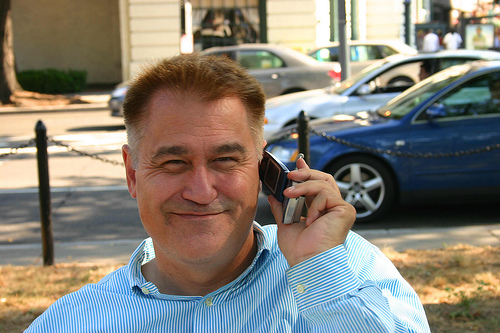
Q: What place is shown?
A: It is a street.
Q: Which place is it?
A: It is a street.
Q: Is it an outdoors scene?
A: Yes, it is outdoors.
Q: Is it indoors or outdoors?
A: It is outdoors.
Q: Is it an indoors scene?
A: No, it is outdoors.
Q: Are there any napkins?
A: No, there are no napkins.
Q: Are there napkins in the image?
A: No, there are no napkins.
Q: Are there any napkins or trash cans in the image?
A: No, there are no napkins or trash cans.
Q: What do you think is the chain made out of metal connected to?
A: The chain is connected to the post.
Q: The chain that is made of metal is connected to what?
A: The chain is connected to the post.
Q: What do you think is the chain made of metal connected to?
A: The chain is connected to the post.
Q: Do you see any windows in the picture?
A: Yes, there is a window.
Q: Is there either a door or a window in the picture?
A: Yes, there is a window.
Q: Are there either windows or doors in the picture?
A: Yes, there is a window.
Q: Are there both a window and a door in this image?
A: No, there is a window but no doors.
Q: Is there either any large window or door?
A: Yes, there is a large window.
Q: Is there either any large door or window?
A: Yes, there is a large window.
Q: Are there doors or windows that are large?
A: Yes, the window is large.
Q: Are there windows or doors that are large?
A: Yes, the window is large.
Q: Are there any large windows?
A: Yes, there is a large window.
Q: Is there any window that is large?
A: Yes, there is a large window.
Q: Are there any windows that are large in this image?
A: Yes, there is a large window.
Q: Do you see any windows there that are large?
A: Yes, there is a window that is large.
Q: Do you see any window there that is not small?
A: Yes, there is a large window.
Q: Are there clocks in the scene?
A: No, there are no clocks.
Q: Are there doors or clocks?
A: No, there are no clocks or doors.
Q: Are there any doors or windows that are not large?
A: No, there is a window but it is large.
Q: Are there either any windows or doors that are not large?
A: No, there is a window but it is large.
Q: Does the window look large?
A: Yes, the window is large.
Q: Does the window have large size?
A: Yes, the window is large.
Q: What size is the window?
A: The window is large.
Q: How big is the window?
A: The window is large.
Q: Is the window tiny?
A: No, the window is large.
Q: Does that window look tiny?
A: No, the window is large.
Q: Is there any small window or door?
A: No, there is a window but it is large.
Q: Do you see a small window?
A: No, there is a window but it is large.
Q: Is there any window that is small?
A: No, there is a window but it is large.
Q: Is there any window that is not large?
A: No, there is a window but it is large.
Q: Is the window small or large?
A: The window is large.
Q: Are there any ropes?
A: No, there are no ropes.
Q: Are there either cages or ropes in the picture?
A: No, there are no ropes or cages.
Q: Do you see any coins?
A: No, there are no coins.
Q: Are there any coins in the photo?
A: No, there are no coins.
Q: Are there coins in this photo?
A: No, there are no coins.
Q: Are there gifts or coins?
A: No, there are no coins or gifts.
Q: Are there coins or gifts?
A: No, there are no coins or gifts.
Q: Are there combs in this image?
A: No, there are no combs.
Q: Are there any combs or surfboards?
A: No, there are no combs or surfboards.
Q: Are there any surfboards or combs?
A: No, there are no combs or surfboards.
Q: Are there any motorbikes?
A: No, there are no motorbikes.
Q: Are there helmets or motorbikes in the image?
A: No, there are no motorbikes or helmets.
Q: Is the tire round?
A: Yes, the tire is round.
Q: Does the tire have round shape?
A: Yes, the tire is round.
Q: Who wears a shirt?
A: The man wears a shirt.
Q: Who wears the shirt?
A: The man wears a shirt.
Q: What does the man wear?
A: The man wears a shirt.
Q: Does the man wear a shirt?
A: Yes, the man wears a shirt.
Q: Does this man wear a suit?
A: No, the man wears a shirt.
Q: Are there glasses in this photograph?
A: No, there are no glasses.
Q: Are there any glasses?
A: No, there are no glasses.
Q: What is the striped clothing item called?
A: The clothing item is a shirt.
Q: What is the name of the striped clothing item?
A: The clothing item is a shirt.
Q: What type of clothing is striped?
A: The clothing is a shirt.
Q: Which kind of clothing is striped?
A: The clothing is a shirt.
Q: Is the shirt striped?
A: Yes, the shirt is striped.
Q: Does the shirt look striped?
A: Yes, the shirt is striped.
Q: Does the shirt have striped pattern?
A: Yes, the shirt is striped.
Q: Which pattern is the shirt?
A: The shirt is striped.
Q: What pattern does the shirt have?
A: The shirt has striped pattern.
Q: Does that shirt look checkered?
A: No, the shirt is striped.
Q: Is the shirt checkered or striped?
A: The shirt is striped.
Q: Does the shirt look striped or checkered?
A: The shirt is striped.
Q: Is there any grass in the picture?
A: Yes, there is grass.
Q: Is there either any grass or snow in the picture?
A: Yes, there is grass.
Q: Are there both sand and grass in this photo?
A: No, there is grass but no sand.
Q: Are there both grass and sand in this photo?
A: No, there is grass but no sand.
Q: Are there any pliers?
A: No, there are no pliers.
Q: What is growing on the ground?
A: The grass is growing on the ground.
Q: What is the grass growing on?
A: The grass is growing on the ground.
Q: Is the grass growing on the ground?
A: Yes, the grass is growing on the ground.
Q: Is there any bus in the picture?
A: No, there are no buses.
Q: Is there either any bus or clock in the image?
A: No, there are no buses or clocks.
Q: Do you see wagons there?
A: No, there are no wagons.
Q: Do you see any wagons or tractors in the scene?
A: No, there are no wagons or tractors.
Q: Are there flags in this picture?
A: No, there are no flags.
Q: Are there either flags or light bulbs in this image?
A: No, there are no flags or light bulbs.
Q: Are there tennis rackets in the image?
A: No, there are no tennis rackets.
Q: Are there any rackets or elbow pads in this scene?
A: No, there are no rackets or elbow pads.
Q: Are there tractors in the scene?
A: No, there are no tractors.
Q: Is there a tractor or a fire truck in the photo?
A: No, there are no tractors or fire trucks.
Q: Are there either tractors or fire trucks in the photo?
A: No, there are no tractors or fire trucks.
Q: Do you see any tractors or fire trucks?
A: No, there are no tractors or fire trucks.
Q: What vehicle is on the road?
A: The vehicle is a car.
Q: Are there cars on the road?
A: Yes, there is a car on the road.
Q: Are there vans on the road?
A: No, there is a car on the road.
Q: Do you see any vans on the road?
A: No, there is a car on the road.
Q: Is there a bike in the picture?
A: No, there are no bikes.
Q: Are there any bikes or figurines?
A: No, there are no bikes or figurines.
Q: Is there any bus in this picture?
A: No, there are no buses.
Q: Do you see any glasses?
A: No, there are no glasses.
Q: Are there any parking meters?
A: No, there are no parking meters.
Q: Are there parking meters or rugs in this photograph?
A: No, there are no parking meters or rugs.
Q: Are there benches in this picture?
A: No, there are no benches.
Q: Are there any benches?
A: No, there are no benches.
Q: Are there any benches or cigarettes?
A: No, there are no benches or cigarettes.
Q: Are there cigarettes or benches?
A: No, there are no benches or cigarettes.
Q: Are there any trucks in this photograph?
A: No, there are no trucks.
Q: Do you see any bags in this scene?
A: No, there are no bags.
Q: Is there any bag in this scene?
A: No, there are no bags.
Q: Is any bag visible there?
A: No, there are no bags.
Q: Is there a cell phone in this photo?
A: Yes, there is a cell phone.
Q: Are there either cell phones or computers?
A: Yes, there is a cell phone.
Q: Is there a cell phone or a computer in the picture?
A: Yes, there is a cell phone.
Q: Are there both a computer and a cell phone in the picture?
A: No, there is a cell phone but no computers.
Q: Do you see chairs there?
A: No, there are no chairs.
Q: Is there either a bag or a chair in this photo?
A: No, there are no chairs or bags.